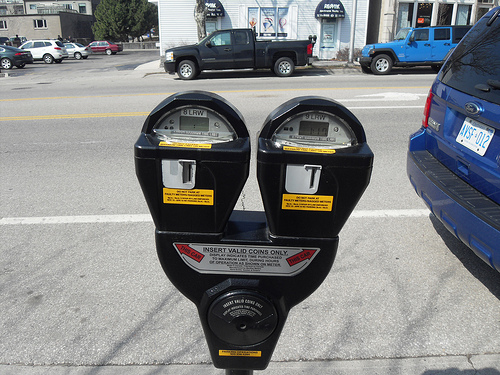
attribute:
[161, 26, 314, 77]
truck — black, parked, pick-up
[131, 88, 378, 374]
meter — parking, double, black, yellow, grey, red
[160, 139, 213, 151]
sticker — yellow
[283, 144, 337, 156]
sticker — yellow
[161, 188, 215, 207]
sticker — yellow, rectangle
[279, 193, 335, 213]
sticker — yellow, rectangle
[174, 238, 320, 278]
sticker — red, white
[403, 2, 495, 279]
ford — blue, parked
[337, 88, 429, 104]
arrow — painted, white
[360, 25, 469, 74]
car — parked, blue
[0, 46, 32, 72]
car — parked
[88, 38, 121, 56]
car — parked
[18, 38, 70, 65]
car — parked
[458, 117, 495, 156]
plate — license, blue, white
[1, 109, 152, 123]
line — yellow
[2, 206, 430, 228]
line — white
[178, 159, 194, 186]
slot — metal, silver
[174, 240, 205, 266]
arrow — red, pointing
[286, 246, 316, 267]
arrow — red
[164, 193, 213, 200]
writing — black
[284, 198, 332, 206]
writing — black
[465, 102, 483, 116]
symbol — blue, silver, ford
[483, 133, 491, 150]
number — blue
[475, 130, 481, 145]
number — blue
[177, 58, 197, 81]
tire — black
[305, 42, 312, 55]
light — rear